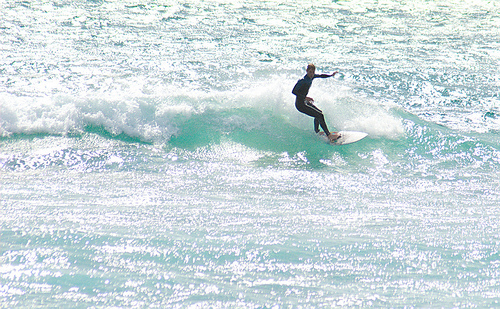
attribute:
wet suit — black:
[294, 76, 326, 128]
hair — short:
[306, 63, 316, 72]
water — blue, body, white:
[7, 4, 497, 306]